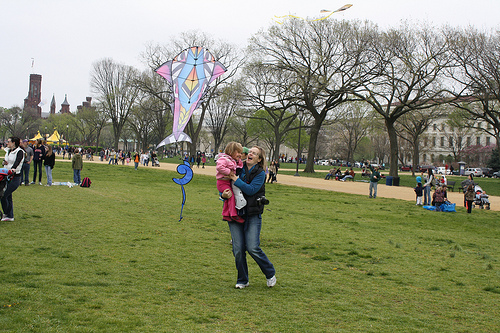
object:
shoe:
[233, 280, 250, 291]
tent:
[46, 127, 69, 146]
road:
[306, 177, 338, 192]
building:
[370, 94, 500, 168]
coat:
[213, 153, 243, 180]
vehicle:
[432, 166, 453, 175]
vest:
[224, 161, 267, 216]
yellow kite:
[271, 3, 353, 24]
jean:
[227, 213, 275, 285]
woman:
[215, 140, 247, 224]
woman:
[0, 136, 25, 222]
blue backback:
[439, 200, 456, 213]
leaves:
[226, 65, 358, 168]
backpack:
[80, 177, 92, 187]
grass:
[10, 200, 401, 331]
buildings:
[19, 72, 44, 124]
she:
[218, 145, 277, 291]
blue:
[171, 164, 193, 223]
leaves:
[241, 13, 419, 174]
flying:
[153, 42, 227, 150]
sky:
[0, 0, 500, 125]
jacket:
[215, 155, 243, 179]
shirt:
[217, 161, 265, 215]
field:
[0, 154, 491, 333]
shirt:
[0, 146, 29, 175]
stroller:
[463, 183, 476, 214]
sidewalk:
[276, 174, 500, 212]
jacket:
[71, 154, 83, 170]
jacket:
[40, 150, 55, 170]